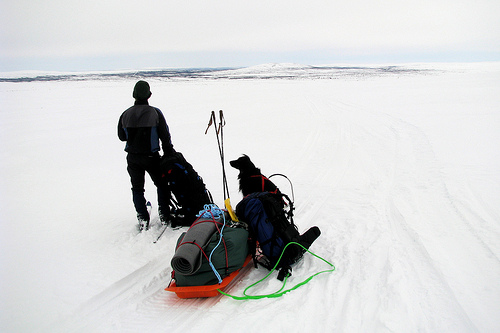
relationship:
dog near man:
[229, 152, 283, 202] [116, 80, 175, 230]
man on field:
[116, 80, 175, 230] [4, 68, 496, 332]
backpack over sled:
[171, 204, 249, 289] [164, 239, 260, 300]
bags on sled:
[171, 226, 249, 288] [155, 195, 285, 312]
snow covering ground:
[339, 94, 446, 156] [1, 67, 481, 322]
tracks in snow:
[113, 256, 288, 331] [1, 61, 500, 332]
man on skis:
[116, 80, 175, 230] [129, 209, 179, 253]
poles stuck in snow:
[195, 105, 246, 233] [273, 113, 452, 193]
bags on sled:
[144, 206, 262, 293] [137, 193, 301, 304]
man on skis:
[116, 80, 175, 230] [130, 197, 178, 245]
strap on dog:
[253, 173, 279, 193] [229, 152, 283, 202]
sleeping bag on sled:
[167, 207, 229, 277] [162, 245, 256, 299]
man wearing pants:
[116, 80, 175, 230] [122, 153, 176, 227]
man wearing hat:
[117, 81, 176, 225] [132, 80, 152, 101]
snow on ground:
[1, 61, 500, 332] [1, 67, 481, 322]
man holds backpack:
[116, 80, 175, 230] [160, 153, 213, 228]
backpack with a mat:
[169, 222, 248, 292] [172, 217, 221, 274]